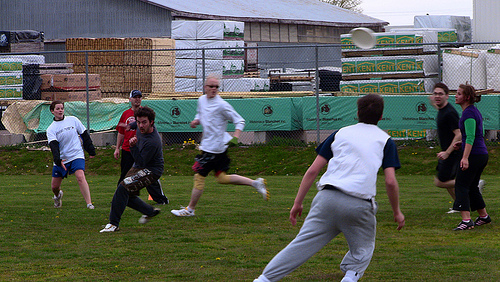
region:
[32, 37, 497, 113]
a metal fence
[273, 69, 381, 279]
a man wearing sweatpants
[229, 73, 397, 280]
a man wearing gray sweatpants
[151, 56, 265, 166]
a person wearing a white long sleeve shirt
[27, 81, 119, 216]
a person wearing black long sleeves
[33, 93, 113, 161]
a person wearing a white shirt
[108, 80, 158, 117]
a person wearing a hat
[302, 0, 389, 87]
a white frisbee in the air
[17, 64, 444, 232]
people standing on the grass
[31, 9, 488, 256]
people playing frisbee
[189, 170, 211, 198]
Man wearing a knee brace.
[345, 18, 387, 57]
White frisbee in the air.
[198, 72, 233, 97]
Man wearing dark sunglasses.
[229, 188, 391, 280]
Man wearing grey sweat pants.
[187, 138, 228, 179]
Man wearing black shorts.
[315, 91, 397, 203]
Man wearing a blue and white shirt.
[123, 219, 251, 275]
Bright green grass on the field.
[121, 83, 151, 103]
Man wearing a baseball hat.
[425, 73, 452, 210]
Man dress all in black.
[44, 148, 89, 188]
Man in royal blue shirt.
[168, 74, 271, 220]
man is wearing sunglasses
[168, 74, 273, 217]
the man is running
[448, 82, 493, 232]
girl's shirt is green and purple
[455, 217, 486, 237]
stripes on woman's shoes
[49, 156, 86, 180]
man's shorts are blue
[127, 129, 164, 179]
man's shirt is gray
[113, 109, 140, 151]
man's shirt is red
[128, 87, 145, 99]
man wearing a hat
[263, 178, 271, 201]
yellow part on bottom of shoe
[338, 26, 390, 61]
frisbee flying in air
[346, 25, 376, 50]
a white flying frisbee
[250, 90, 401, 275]
a man in gray sweatpants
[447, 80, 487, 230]
a woman in a shirt with green sleeves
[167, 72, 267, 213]
man in white shirt and sunglasses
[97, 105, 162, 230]
a man in dark pants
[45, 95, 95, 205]
a person in white shirt and blue shorts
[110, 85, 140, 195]
man in a red shirt and wearing a cap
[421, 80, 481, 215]
man in glasses and dark shirt and shorts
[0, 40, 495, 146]
chain link fence behind the frisbee players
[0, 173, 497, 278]
grass field the people are playing in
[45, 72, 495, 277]
seven men and women playing a sport on the field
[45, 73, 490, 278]
women and men playing a Frisbee game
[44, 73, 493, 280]
people playing Frisbee in a park area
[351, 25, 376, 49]
a white Frisbee disc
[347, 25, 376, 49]
a Frisbee in the air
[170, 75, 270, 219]
a man in a white long sleeve shirt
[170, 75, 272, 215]
a man running on the field to catch a Frisbee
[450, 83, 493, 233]
a woman playing a Frisbee game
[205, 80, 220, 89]
black sunglasses on the man's eyes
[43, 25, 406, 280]
players running to retrieve a white Frisbee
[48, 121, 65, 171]
arm of a man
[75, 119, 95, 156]
arm of a man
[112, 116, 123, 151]
arm of a man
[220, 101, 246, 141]
arm of a man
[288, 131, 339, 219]
arm of a man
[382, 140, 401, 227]
arm of a man